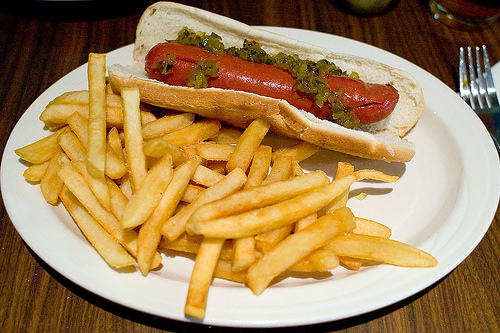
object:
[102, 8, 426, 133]
dog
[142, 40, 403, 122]
hot dog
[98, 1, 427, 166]
bun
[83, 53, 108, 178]
fries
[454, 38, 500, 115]
fork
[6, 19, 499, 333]
plate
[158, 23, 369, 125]
relish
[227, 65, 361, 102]
light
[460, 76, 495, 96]
light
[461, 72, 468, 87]
stain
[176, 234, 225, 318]
french fry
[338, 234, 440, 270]
french fry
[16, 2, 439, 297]
use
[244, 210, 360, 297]
french fries